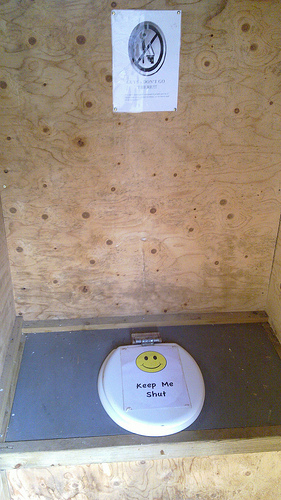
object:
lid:
[97, 341, 206, 440]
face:
[135, 349, 168, 374]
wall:
[0, 3, 281, 319]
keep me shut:
[134, 378, 174, 405]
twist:
[129, 327, 164, 349]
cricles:
[64, 30, 113, 126]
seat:
[5, 324, 281, 440]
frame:
[0, 308, 281, 451]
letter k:
[135, 378, 143, 391]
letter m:
[161, 376, 172, 388]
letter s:
[144, 389, 152, 398]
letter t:
[162, 387, 167, 402]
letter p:
[151, 380, 156, 395]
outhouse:
[0, 0, 281, 498]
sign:
[112, 10, 182, 111]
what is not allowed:
[126, 20, 165, 75]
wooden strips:
[16, 311, 272, 336]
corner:
[246, 305, 274, 333]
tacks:
[253, 306, 274, 320]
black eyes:
[142, 353, 158, 361]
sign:
[120, 342, 191, 412]